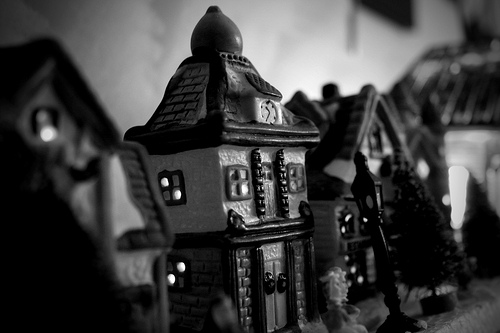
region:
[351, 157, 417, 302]
Black toy lamp post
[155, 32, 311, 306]
Two toned toy house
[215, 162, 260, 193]
Windows on a toy house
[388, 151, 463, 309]
Tree next to a toy house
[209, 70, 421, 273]
Two toy houses next to each other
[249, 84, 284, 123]
Clock on a toy house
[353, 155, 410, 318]
Lamp in front of house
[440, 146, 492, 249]
Tree in between two toy houses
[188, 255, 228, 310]
Brick faced on a toy house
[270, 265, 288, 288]
Handles on a door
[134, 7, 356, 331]
figurine of a building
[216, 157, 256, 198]
small window on the building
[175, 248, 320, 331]
bottom half of the building is brick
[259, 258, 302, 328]
door has two sides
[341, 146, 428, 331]
small black street lamp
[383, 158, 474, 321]
pine tree in a planter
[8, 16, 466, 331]
row of buildings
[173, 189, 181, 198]
light shining in the window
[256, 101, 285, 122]
clock on top of the building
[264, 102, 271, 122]
two black clock hands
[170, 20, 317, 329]
a small doll in series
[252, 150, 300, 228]
a small door in doll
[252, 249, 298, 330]
ground entrance on doll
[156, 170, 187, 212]
windows in the doll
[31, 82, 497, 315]
a group of dolls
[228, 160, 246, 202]
front windows of the doll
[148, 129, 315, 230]
top floor of the doll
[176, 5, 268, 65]
top pillar of the doll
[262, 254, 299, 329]
a clean design on door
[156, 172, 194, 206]
lightnings inside the window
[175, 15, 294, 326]
this is a toy house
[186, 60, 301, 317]
the house is tall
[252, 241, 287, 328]
the door is closed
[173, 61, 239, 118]
this is the roof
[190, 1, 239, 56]
this is the antennae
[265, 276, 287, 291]
the handle are black in color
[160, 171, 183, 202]
the window is closed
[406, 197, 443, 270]
this is a tree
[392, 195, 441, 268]
the tree is slanting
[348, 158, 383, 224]
this is a street light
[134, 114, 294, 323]
a house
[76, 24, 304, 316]
a house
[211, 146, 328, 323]
a house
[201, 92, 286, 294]
a house